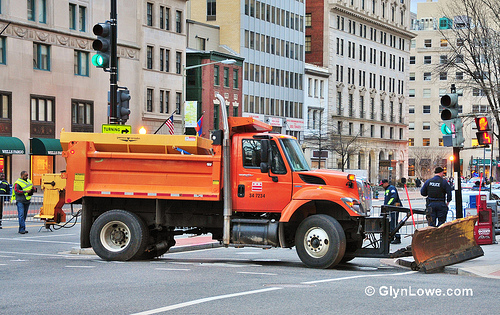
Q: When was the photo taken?
A: Daytime.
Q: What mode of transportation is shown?
A: Truck.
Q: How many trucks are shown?
A: One.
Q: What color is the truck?
A: Orange.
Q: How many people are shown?
A: Three.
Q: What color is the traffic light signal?
A: Green.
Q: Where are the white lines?
A: Street.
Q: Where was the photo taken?
A: On the street.